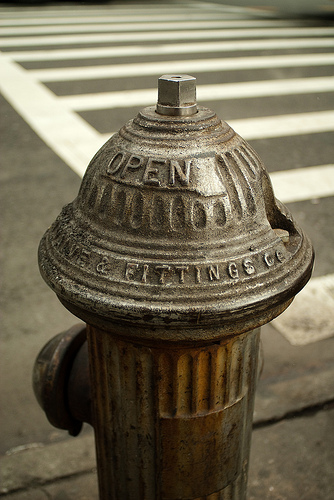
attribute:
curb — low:
[2, 366, 331, 495]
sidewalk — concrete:
[0, 368, 333, 498]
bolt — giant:
[153, 71, 200, 115]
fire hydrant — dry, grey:
[32, 73, 319, 499]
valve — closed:
[22, 313, 94, 439]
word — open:
[104, 154, 197, 186]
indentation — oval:
[113, 184, 125, 227]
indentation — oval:
[128, 186, 144, 230]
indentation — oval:
[149, 195, 165, 231]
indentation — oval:
[169, 196, 186, 235]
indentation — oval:
[190, 196, 208, 231]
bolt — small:
[265, 227, 293, 244]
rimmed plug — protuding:
[30, 324, 87, 442]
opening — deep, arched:
[252, 182, 290, 248]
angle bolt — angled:
[153, 70, 204, 116]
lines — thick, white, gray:
[6, 3, 333, 349]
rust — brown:
[141, 361, 250, 473]